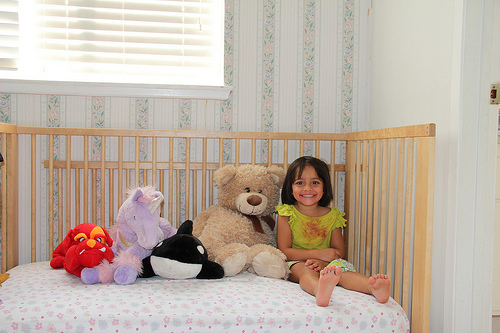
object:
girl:
[276, 155, 391, 306]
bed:
[0, 122, 434, 332]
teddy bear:
[191, 164, 289, 279]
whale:
[136, 220, 225, 280]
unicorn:
[81, 185, 178, 285]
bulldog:
[50, 223, 115, 278]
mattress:
[0, 261, 410, 333]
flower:
[164, 316, 170, 323]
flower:
[56, 313, 63, 319]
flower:
[258, 317, 265, 323]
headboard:
[16, 126, 350, 265]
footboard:
[44, 161, 368, 261]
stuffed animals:
[51, 165, 293, 284]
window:
[0, 0, 223, 87]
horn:
[148, 195, 164, 213]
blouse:
[272, 203, 347, 250]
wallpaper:
[0, 1, 354, 267]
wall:
[229, 0, 361, 117]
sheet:
[1, 261, 408, 333]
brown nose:
[247, 195, 262, 206]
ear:
[214, 164, 238, 188]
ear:
[268, 164, 287, 186]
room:
[0, 0, 500, 331]